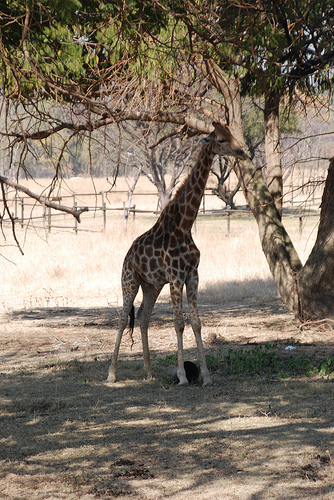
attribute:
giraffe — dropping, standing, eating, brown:
[106, 118, 252, 390]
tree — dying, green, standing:
[1, 0, 333, 325]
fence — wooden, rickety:
[4, 190, 334, 234]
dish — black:
[177, 360, 200, 385]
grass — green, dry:
[151, 337, 332, 381]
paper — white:
[283, 343, 297, 352]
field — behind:
[6, 170, 327, 278]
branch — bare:
[2, 107, 221, 158]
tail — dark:
[126, 302, 138, 352]